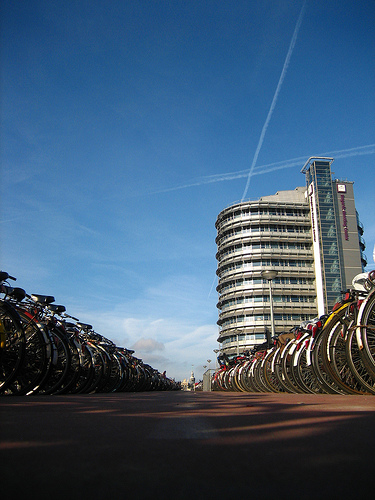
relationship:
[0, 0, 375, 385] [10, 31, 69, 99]
cloud in sky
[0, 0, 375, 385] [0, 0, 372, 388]
cloud in sky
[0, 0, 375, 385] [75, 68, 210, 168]
cloud in sky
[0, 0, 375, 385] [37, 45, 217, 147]
cloud in sky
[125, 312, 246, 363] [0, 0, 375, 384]
cloud in blue sky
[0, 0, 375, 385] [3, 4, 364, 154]
cloud in blue sky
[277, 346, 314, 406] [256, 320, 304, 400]
tire on bike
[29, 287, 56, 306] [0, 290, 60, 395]
seat on bike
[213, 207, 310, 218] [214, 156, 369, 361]
windows on building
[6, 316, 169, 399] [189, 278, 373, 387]
tire on bike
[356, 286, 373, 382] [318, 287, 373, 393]
tire on bike